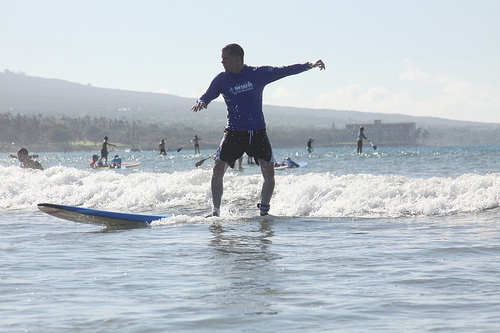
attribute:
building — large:
[342, 117, 422, 147]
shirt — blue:
[198, 62, 312, 126]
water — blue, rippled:
[2, 212, 499, 331]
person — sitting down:
[275, 154, 305, 168]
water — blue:
[0, 133, 499, 175]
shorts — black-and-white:
[211, 127, 278, 167]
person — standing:
[185, 127, 213, 170]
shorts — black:
[221, 129, 272, 163]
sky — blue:
[0, 2, 496, 114]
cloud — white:
[328, 66, 497, 96]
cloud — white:
[18, 16, 217, 63]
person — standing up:
[154, 133, 169, 156]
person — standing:
[191, 44, 325, 215]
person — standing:
[200, 31, 296, 216]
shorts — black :
[218, 130, 273, 168]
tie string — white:
[245, 127, 255, 141]